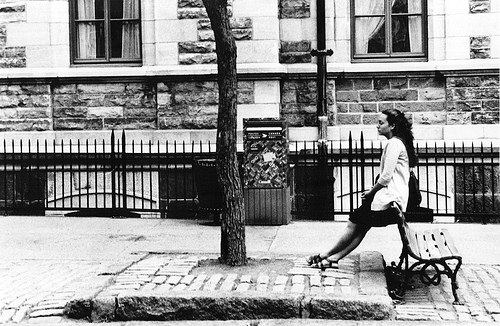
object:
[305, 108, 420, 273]
lady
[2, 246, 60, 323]
floor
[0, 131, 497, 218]
fence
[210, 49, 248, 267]
tree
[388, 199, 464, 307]
bench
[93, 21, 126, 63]
open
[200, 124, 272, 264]
center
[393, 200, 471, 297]
standing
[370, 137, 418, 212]
shirt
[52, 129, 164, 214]
gate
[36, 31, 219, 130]
building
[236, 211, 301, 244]
these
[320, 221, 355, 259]
legs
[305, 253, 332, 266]
shoes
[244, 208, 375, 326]
these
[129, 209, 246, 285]
these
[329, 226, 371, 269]
legs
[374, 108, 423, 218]
hair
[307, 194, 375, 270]
crossed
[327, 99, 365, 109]
right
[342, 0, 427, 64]
window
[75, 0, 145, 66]
window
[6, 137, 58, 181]
left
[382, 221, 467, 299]
empty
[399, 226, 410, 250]
brown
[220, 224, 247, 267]
bottom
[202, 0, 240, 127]
top